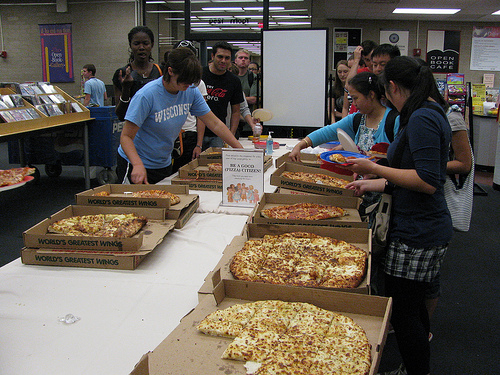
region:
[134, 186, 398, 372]
Three pizzas sitting in boxes on table.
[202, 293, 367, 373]
Cheese pizza in box.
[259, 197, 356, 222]
Pepperoni pizza in box.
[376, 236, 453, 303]
Girl dressed in blue plaid skirt.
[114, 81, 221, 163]
Girl dressed in blue t-shirt with white writing.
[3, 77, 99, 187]
Magazines and books on rack.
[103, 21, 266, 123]
People in line waiting to get pizza.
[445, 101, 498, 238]
Girl with white purse over shoulder.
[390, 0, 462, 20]
Light mounted in ceiling of room.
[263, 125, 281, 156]
Plastic bottle of hand sanitizer sitting on table.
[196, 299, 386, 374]
Cheese pizza in box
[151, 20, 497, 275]
People take slices of pizza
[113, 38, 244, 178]
woman's shirt says Wisconsin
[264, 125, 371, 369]
Five pizzas in a row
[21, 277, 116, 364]
white table cloth on table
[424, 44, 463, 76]
open book cafe sign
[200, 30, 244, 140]
man wears coca cola zero shirt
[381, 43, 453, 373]
woman in black leggings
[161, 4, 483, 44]
white overhead fluorescent lights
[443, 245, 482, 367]
grey carpet in room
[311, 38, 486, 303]
People buying pizza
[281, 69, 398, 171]
Woman take a slice of pizza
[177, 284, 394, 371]
Pizza is cut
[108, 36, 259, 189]
Woman serving pizza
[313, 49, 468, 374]
Woman with a blue dish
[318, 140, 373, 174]
Dish has a slice of pizza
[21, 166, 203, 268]
Boxed with large pizzas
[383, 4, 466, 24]
Light in the ceiling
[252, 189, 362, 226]
Pepperoni cheese pizza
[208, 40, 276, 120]
People behind looking pizzas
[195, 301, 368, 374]
very large cheese pizza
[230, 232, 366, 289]
very large cheese pizza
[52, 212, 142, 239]
very large cheese pizza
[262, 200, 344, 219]
large pepperoni pizza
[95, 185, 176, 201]
very large cheese pizza sliced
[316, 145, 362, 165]
blue and white paper plate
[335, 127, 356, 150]
white thin paper plate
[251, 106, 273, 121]
white thin paper plate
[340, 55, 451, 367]
brown haired woman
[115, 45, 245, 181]
brown haired average woman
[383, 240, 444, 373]
black leggings under a plaid skirt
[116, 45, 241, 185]
girl wearing a light blue t-shirt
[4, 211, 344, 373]
open pizza boxes on table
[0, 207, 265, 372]
white tablecloth on table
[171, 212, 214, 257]
wrinkle on tablecloth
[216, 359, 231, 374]
grease spot on pizza box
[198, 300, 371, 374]
cheese pizza on table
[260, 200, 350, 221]
pepperoni pizza in box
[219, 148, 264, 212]
sign on table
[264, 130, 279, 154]
bottle of hand sanitizer on table